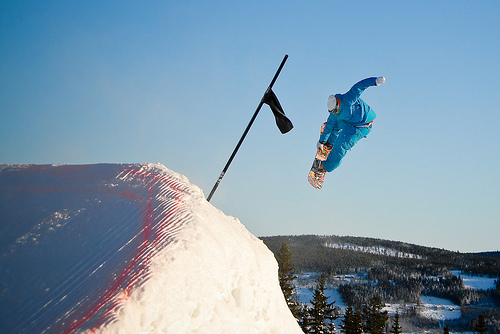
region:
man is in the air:
[309, 76, 384, 188]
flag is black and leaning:
[205, 52, 292, 202]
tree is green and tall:
[275, 244, 304, 321]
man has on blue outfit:
[320, 76, 375, 173]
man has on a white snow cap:
[326, 96, 339, 113]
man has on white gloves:
[375, 74, 384, 84]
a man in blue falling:
[304, 70, 394, 192]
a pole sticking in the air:
[202, 48, 300, 209]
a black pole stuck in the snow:
[165, 50, 309, 331]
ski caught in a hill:
[125, 45, 303, 323]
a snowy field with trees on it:
[262, 223, 496, 331]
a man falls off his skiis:
[197, 51, 408, 216]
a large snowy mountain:
[8, 161, 309, 331]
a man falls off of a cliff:
[205, 48, 397, 316]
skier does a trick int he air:
[194, 38, 401, 240]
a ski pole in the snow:
[201, 43, 301, 230]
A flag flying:
[222, 74, 312, 137]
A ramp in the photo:
[70, 169, 135, 271]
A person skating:
[312, 69, 395, 186]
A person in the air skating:
[309, 68, 395, 203]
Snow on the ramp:
[182, 211, 257, 308]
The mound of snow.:
[9, 158, 316, 329]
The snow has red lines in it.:
[9, 158, 191, 225]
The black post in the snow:
[206, 48, 302, 225]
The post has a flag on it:
[258, 89, 292, 129]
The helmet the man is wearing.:
[318, 94, 335, 111]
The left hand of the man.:
[318, 113, 335, 148]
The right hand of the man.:
[348, 73, 388, 93]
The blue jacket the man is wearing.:
[326, 75, 379, 124]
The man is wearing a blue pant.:
[318, 123, 372, 164]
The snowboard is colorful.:
[308, 117, 335, 185]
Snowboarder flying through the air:
[302, 72, 387, 191]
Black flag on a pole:
[262, 91, 294, 135]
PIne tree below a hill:
[303, 280, 335, 330]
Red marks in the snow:
[100, 162, 182, 242]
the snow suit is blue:
[313, 78, 381, 166]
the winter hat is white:
[326, 92, 338, 114]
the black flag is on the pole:
[202, 53, 294, 186]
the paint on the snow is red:
[101, 164, 182, 301]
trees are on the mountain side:
[297, 240, 453, 293]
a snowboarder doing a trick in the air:
[307, 67, 396, 190]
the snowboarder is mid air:
[309, 75, 384, 186]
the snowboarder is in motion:
[309, 73, 384, 189]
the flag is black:
[263, 88, 293, 133]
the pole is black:
[208, 53, 288, 201]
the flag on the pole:
[206, 51, 294, 204]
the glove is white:
[376, 75, 384, 84]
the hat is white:
[326, 94, 336, 111]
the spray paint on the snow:
[2, 162, 300, 332]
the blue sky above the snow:
[1, 0, 499, 332]